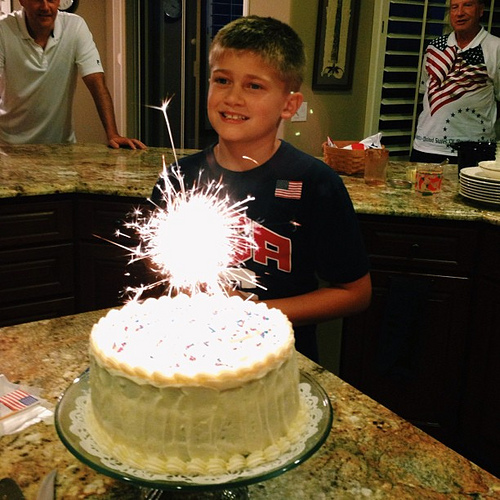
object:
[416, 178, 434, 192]
peppers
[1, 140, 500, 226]
countertop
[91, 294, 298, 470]
cake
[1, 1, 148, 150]
man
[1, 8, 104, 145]
polo shirt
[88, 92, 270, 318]
sparkler candle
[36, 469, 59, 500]
knife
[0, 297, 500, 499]
countertop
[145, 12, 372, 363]
child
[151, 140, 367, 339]
t-shirt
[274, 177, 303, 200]
flag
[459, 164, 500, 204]
plates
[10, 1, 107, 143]
wall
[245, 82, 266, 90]
eye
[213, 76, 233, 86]
eye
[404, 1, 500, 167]
man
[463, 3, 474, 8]
eye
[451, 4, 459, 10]
eye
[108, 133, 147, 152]
hand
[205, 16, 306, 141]
head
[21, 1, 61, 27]
head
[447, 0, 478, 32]
head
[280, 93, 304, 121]
ear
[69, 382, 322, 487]
doily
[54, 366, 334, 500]
cake stand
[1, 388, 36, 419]
american flag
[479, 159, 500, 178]
bowl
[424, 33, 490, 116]
flag graphic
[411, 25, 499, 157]
polo shirt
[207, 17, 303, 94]
hair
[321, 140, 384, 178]
basket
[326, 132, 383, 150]
snacks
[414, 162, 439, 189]
glass